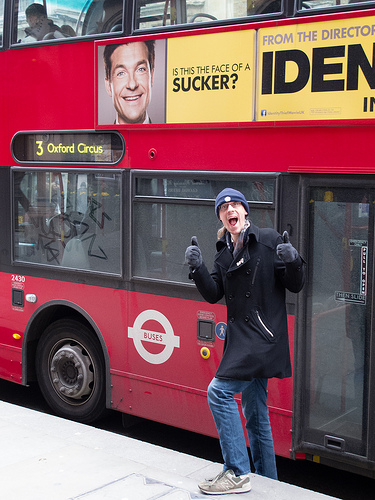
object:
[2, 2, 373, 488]
bus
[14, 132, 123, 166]
sign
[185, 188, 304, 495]
man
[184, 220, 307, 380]
coat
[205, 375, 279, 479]
jeans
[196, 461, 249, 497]
foot wear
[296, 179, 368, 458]
door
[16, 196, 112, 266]
graffiti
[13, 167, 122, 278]
window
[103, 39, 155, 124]
actor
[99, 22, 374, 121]
movie ad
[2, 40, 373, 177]
side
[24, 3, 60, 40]
passenger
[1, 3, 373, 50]
upper level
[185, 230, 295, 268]
thumbs up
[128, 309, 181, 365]
sign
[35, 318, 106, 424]
tire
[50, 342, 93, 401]
hubcap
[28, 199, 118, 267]
drawings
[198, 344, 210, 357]
button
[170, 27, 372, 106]
ad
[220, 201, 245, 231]
face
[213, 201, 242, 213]
eyes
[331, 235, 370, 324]
signs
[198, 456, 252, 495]
shoe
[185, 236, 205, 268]
glove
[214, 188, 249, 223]
cap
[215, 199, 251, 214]
eyeglasses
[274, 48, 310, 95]
letter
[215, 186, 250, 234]
head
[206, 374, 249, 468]
leg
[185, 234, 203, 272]
hand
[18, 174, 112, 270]
writing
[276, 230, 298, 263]
gloves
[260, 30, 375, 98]
writing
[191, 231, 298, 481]
attire